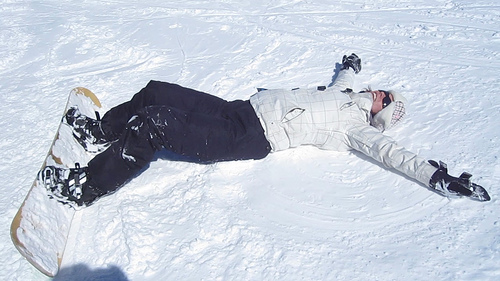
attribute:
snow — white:
[6, 4, 496, 280]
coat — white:
[243, 58, 448, 185]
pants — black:
[61, 80, 268, 207]